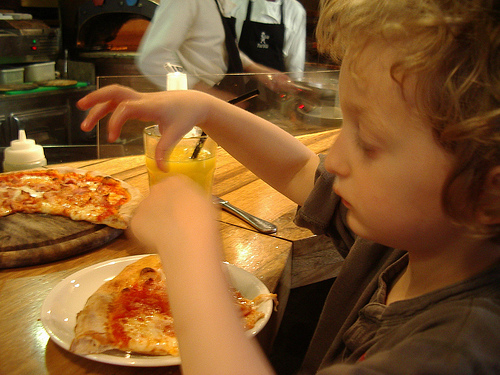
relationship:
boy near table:
[72, 1, 500, 374] [1, 130, 342, 374]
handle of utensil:
[221, 199, 278, 235] [211, 192, 278, 234]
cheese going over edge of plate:
[254, 290, 281, 308] [40, 251, 272, 367]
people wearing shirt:
[133, 0, 307, 116] [222, 0, 305, 80]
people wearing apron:
[133, 0, 307, 116] [212, 1, 247, 97]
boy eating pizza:
[72, 1, 498, 373] [67, 251, 271, 338]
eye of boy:
[353, 123, 381, 161] [72, 1, 498, 373]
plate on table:
[34, 238, 297, 368] [79, 131, 366, 311]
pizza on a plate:
[72, 252, 279, 357] [71, 252, 136, 373]